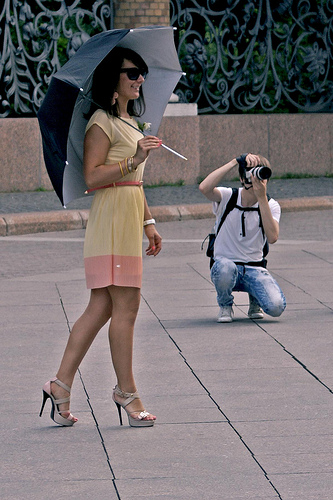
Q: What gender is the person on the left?
A: Female.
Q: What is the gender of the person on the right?
A: Male.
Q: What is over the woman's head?
A: Umbrella.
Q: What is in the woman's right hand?
A: Umbrella handle.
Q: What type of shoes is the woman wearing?
A: High heals.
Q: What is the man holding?
A: Camera.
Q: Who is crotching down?
A: The man.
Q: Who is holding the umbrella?
A: The woman.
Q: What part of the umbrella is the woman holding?
A: The handle.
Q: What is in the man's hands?
A: A camera.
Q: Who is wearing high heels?
A: The woman.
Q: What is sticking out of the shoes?
A: Toes.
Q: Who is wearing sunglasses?
A: The woman.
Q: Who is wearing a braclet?
A: The woman.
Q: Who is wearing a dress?
A: The woman.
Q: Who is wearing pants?
A: The man.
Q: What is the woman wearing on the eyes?
A: Sunglasses.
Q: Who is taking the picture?
A: A man.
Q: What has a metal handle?
A: A umbrella.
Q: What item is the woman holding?
A: A umbrella.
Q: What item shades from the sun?
A: A umbrella.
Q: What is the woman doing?
A: Taking a picture.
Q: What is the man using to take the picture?
A: A camera.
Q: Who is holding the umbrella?
A: Woman.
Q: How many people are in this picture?
A: 2.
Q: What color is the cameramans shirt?
A: White.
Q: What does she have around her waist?
A: Belt.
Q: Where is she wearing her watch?
A: Wrist.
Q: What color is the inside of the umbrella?
A: White.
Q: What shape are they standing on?
A: Square.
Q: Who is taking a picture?
A: Man.